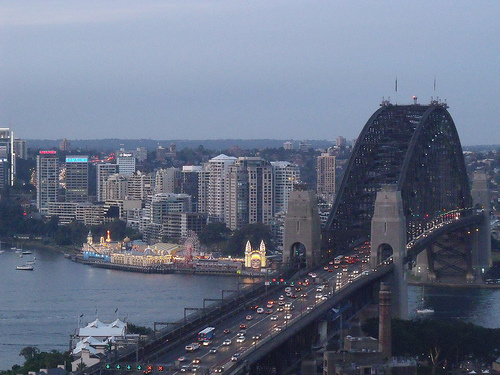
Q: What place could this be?
A: It is a city.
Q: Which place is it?
A: It is a city.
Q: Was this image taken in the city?
A: Yes, it was taken in the city.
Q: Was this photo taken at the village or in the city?
A: It was taken at the city.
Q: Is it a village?
A: No, it is a city.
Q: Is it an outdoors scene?
A: Yes, it is outdoors.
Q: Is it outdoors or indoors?
A: It is outdoors.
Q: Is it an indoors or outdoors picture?
A: It is outdoors.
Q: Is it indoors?
A: No, it is outdoors.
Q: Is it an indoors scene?
A: No, it is outdoors.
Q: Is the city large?
A: Yes, the city is large.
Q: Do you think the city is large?
A: Yes, the city is large.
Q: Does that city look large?
A: Yes, the city is large.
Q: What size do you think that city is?
A: The city is large.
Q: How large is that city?
A: The city is large.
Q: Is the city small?
A: No, the city is large.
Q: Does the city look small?
A: No, the city is large.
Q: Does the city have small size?
A: No, the city is large.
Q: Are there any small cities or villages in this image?
A: No, there is a city but it is large.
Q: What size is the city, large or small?
A: The city is large.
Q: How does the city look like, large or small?
A: The city is large.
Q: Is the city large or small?
A: The city is large.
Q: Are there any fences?
A: No, there are no fences.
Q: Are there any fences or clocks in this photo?
A: No, there are no fences or clocks.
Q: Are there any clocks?
A: No, there are no clocks.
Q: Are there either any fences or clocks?
A: No, there are no clocks or fences.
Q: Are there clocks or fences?
A: No, there are no clocks or fences.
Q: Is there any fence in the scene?
A: No, there are no fences.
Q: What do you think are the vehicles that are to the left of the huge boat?
A: The vehicles are cars.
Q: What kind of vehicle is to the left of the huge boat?
A: The vehicles are cars.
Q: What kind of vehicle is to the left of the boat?
A: The vehicles are cars.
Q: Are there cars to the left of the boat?
A: Yes, there are cars to the left of the boat.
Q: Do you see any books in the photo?
A: No, there are no books.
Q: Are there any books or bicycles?
A: No, there are no books or bicycles.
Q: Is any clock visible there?
A: No, there are no clocks.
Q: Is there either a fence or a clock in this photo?
A: No, there are no clocks or fences.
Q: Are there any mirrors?
A: No, there are no mirrors.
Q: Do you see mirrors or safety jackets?
A: No, there are no mirrors or safety jackets.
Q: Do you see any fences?
A: No, there are no fences.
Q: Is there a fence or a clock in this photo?
A: No, there are no fences or clocks.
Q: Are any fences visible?
A: No, there are no fences.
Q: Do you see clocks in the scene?
A: No, there are no clocks.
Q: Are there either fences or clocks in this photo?
A: No, there are no clocks or fences.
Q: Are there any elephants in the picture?
A: No, there are no elephants.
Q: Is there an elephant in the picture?
A: No, there are no elephants.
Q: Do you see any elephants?
A: No, there are no elephants.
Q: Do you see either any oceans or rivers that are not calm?
A: No, there is a river but it is calm.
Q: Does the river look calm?
A: Yes, the river is calm.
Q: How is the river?
A: The river is calm.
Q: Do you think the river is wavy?
A: No, the river is calm.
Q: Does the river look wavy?
A: No, the river is calm.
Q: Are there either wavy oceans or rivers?
A: No, there is a river but it is calm.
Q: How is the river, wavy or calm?
A: The river is calm.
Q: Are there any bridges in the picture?
A: Yes, there is a bridge.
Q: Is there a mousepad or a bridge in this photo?
A: Yes, there is a bridge.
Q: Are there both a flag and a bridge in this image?
A: No, there is a bridge but no flags.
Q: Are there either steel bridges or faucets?
A: Yes, there is a steel bridge.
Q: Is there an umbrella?
A: No, there are no umbrellas.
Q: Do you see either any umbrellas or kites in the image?
A: No, there are no umbrellas or kites.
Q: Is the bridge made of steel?
A: Yes, the bridge is made of steel.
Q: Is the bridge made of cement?
A: No, the bridge is made of steel.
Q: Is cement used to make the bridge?
A: No, the bridge is made of steel.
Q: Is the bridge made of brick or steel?
A: The bridge is made of steel.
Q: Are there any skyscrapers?
A: Yes, there is a skyscraper.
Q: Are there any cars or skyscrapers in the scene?
A: Yes, there is a skyscraper.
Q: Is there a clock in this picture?
A: No, there are no clocks.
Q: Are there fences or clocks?
A: No, there are no clocks or fences.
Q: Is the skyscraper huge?
A: Yes, the skyscraper is huge.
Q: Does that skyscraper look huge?
A: Yes, the skyscraper is huge.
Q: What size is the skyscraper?
A: The skyscraper is huge.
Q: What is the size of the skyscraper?
A: The skyscraper is huge.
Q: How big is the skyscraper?
A: The skyscraper is huge.